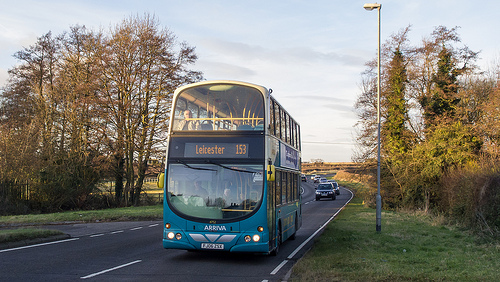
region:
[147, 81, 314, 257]
A large double decker bus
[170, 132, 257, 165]
Bus destination sign reading Leicester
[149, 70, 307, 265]
Arriva brand bus number 153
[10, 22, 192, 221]
Nearly barren, brown trees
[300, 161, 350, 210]
A row of traffic in the close distance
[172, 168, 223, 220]
Bus driver of a double decker bus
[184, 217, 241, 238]
A logo for the British bus company Arriva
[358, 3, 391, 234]
Tall unlit street lamp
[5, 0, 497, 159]
Clear skies in the daylight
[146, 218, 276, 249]
Headlights on the front of a bus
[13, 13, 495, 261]
a scene during the day time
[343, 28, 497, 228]
some trees on the side of the road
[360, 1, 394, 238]
a gray lamp post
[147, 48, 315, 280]
a blue double decker bus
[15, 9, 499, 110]
a sky with clouds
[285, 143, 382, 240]
some traffic behind bus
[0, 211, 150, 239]
an off road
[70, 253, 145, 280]
a white line on street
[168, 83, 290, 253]
blue double deck bus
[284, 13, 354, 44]
white clouds in blue sky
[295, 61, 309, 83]
white clouds in blue sky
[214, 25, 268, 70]
white clouds in blue sky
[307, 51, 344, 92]
white clouds in blue sky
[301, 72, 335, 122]
white clouds in blue sky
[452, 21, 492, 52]
white clouds in blue sky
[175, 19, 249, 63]
white clouds in blue sky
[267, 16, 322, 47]
white clouds in blue sky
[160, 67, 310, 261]
bus on the road.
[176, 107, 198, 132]
Man riding the bus.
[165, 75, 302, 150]
Upper level on the bus.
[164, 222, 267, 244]
Headlights on the bus.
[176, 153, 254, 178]
black wipers on the bus.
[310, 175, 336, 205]
Cars behind the bus.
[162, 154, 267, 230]
Window on the front of the bus.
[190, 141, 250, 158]
lighted sign on the bus.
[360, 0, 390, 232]
Street light beside the road.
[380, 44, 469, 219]
Trees on the side of the road.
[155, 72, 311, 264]
bus on a street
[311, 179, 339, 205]
car on a street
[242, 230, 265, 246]
front headlight on a bus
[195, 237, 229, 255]
front licence plate on a bus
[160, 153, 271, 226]
front windshield on a bus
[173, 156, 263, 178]
windshield wipers on a bus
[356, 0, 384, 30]
street light on a pole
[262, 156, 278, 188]
side rear view mirror on a bus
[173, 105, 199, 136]
person sitting in a bus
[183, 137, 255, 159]
lettering and numbers on a bus